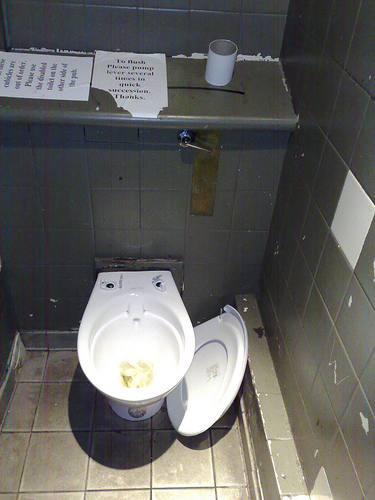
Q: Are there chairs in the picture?
A: No, there are no chairs.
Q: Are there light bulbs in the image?
A: No, there are no light bulbs.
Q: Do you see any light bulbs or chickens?
A: No, there are no light bulbs or chickens.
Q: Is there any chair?
A: No, there are no chairs.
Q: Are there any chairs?
A: No, there are no chairs.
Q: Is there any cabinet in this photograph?
A: No, there are no cabinets.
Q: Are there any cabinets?
A: No, there are no cabinets.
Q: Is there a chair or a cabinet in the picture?
A: No, there are no cabinets or chairs.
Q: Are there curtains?
A: No, there are no curtains.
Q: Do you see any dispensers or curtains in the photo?
A: No, there are no curtains or dispensers.